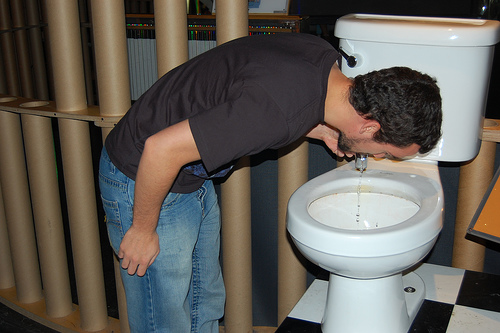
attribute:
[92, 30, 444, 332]
man — a brunette, vomiting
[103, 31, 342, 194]
t-shirt — black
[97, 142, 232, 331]
jeans — blue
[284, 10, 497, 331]
toilet — on display, white, for a bathroom, seatless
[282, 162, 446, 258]
toilet bowl — porcelain, white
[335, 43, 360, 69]
handle — for flushing, silver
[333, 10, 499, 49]
toilet top — white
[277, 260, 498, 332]
tiles — black, white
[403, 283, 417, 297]
bolt — metal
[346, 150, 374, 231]
liquid — falling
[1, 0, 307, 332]
tubing — cardboard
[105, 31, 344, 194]
shirt — gray, brown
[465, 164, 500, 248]
sign — orange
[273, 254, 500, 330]
platform — white, black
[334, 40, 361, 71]
lever — silver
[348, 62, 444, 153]
hair — short, dark